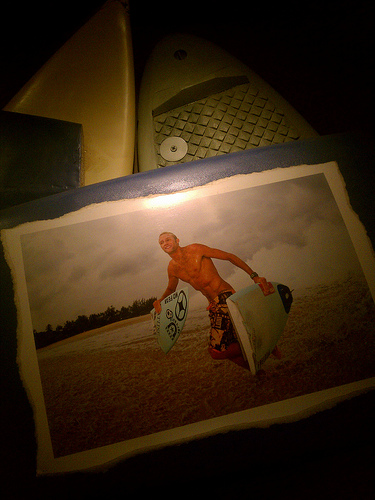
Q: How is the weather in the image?
A: It is cloudy.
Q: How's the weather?
A: It is cloudy.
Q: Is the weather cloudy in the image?
A: Yes, it is cloudy.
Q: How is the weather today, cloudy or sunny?
A: It is cloudy.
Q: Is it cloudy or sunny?
A: It is cloudy.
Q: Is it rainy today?
A: No, it is cloudy.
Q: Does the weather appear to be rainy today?
A: No, it is cloudy.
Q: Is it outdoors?
A: Yes, it is outdoors.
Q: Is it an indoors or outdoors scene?
A: It is outdoors.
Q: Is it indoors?
A: No, it is outdoors.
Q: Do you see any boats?
A: No, there are no boats.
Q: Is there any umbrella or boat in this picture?
A: No, there are no boats or umbrellas.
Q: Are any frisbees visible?
A: No, there are no frisbees.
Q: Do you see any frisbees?
A: No, there are no frisbees.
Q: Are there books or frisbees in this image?
A: No, there are no frisbees or books.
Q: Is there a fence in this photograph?
A: No, there are no fences.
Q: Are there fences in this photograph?
A: No, there are no fences.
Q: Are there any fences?
A: No, there are no fences.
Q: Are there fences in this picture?
A: No, there are no fences.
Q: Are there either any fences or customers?
A: No, there are no fences or customers.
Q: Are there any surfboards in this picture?
A: Yes, there is a surfboard.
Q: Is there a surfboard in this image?
A: Yes, there is a surfboard.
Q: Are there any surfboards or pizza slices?
A: Yes, there is a surfboard.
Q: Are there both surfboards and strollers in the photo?
A: No, there is a surfboard but no strollers.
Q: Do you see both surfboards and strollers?
A: No, there is a surfboard but no strollers.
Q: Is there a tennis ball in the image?
A: No, there are no tennis balls.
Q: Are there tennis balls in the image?
A: No, there are no tennis balls.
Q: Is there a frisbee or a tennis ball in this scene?
A: No, there are no tennis balls or frisbees.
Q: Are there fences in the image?
A: No, there are no fences.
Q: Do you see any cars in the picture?
A: No, there are no cars.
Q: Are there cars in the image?
A: No, there are no cars.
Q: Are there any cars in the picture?
A: No, there are no cars.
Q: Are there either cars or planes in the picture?
A: No, there are no cars or planes.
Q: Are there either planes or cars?
A: No, there are no cars or planes.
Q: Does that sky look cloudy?
A: Yes, the sky is cloudy.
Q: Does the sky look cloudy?
A: Yes, the sky is cloudy.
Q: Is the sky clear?
A: No, the sky is cloudy.